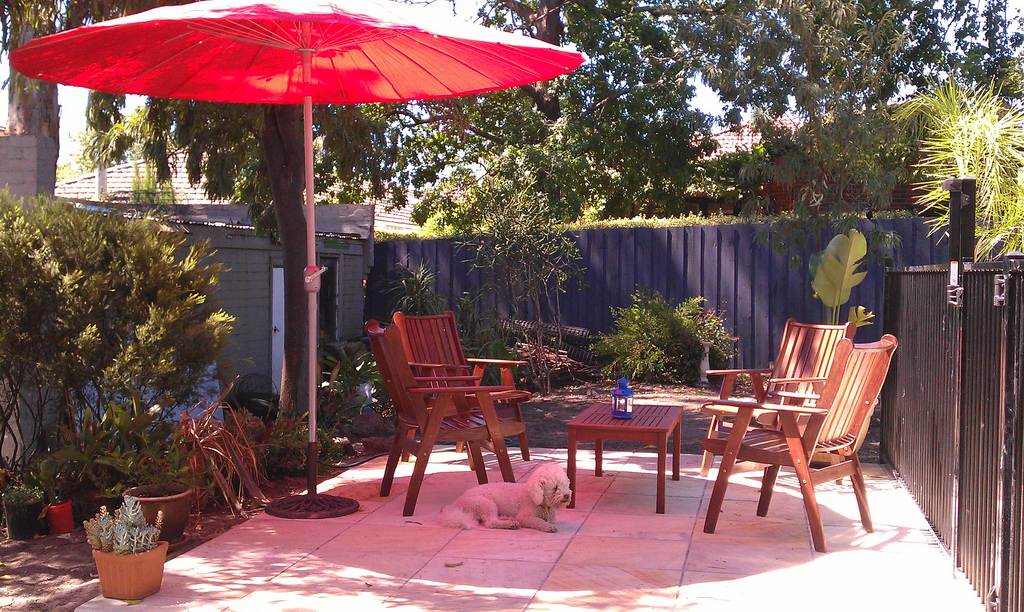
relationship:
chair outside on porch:
[363, 296, 538, 554] [270, 233, 664, 601]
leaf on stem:
[811, 129, 827, 155] [795, 161, 904, 309]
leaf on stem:
[81, 393, 108, 448] [58, 399, 119, 538]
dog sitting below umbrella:
[445, 435, 582, 540] [155, 60, 633, 199]